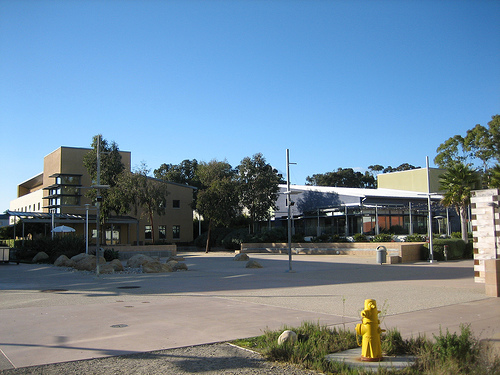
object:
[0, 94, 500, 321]
building.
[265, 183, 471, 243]
building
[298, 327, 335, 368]
grass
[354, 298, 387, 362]
fire hydrant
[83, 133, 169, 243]
tree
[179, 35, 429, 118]
sky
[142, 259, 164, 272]
keyrock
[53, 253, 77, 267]
keyrock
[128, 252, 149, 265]
keyrock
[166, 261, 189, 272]
keyrock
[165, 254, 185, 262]
keyrock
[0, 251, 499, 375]
lot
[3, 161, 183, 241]
windows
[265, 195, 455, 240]
windows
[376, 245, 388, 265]
garbage can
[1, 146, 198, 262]
building